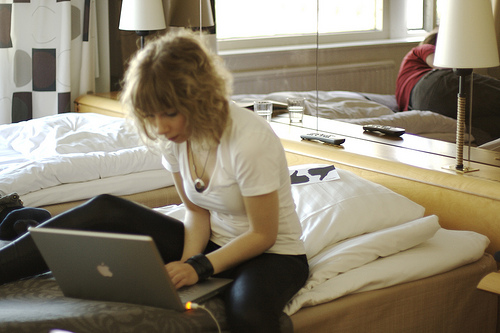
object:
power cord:
[185, 297, 222, 333]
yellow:
[184, 302, 198, 312]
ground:
[475, 126, 492, 138]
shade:
[430, 2, 499, 69]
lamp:
[430, 0, 498, 179]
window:
[213, 0, 384, 40]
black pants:
[0, 193, 313, 333]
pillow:
[289, 164, 424, 252]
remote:
[300, 133, 345, 145]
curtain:
[0, 4, 117, 124]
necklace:
[189, 138, 213, 192]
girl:
[0, 30, 312, 331]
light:
[185, 301, 192, 310]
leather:
[183, 255, 215, 283]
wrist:
[185, 257, 212, 271]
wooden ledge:
[74, 98, 500, 253]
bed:
[0, 122, 497, 331]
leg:
[224, 242, 310, 333]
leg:
[0, 193, 207, 283]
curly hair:
[121, 29, 230, 147]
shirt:
[160, 102, 306, 255]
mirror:
[103, 2, 499, 167]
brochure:
[288, 164, 341, 186]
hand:
[308, 165, 335, 180]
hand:
[291, 170, 310, 184]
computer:
[24, 227, 234, 312]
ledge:
[285, 147, 497, 212]